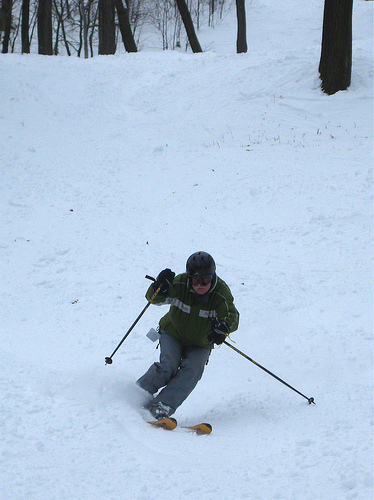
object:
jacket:
[143, 271, 240, 351]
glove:
[206, 318, 231, 346]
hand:
[206, 319, 229, 346]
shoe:
[142, 400, 170, 421]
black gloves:
[152, 268, 175, 297]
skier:
[134, 249, 240, 419]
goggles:
[189, 275, 213, 287]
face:
[191, 275, 212, 295]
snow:
[4, 390, 358, 498]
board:
[146, 417, 178, 431]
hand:
[156, 267, 176, 291]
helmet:
[185, 250, 216, 276]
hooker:
[308, 396, 315, 404]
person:
[134, 249, 241, 421]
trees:
[232, 0, 249, 55]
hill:
[0, 3, 372, 498]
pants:
[134, 326, 211, 421]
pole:
[223, 340, 317, 406]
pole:
[104, 282, 163, 366]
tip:
[204, 423, 212, 431]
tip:
[169, 417, 177, 425]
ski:
[146, 416, 179, 430]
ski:
[181, 422, 213, 435]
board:
[180, 422, 213, 437]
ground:
[0, 0, 374, 500]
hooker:
[104, 356, 113, 365]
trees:
[316, 0, 356, 96]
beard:
[195, 286, 204, 290]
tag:
[145, 327, 161, 343]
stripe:
[198, 309, 218, 320]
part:
[148, 406, 169, 420]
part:
[181, 422, 213, 436]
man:
[132, 250, 240, 423]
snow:
[0, 53, 374, 500]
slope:
[1, 57, 152, 232]